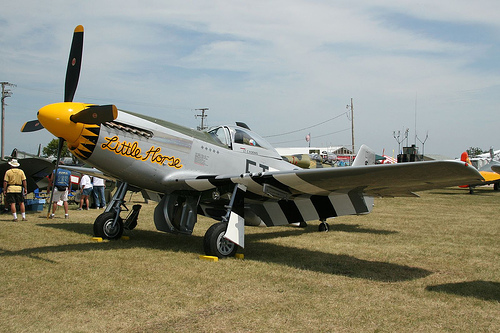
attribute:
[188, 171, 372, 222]
stripe — black, white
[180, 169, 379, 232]
stripes — black, white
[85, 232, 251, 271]
blocks — yellow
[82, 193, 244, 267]
wheels — black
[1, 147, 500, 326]
grass — greenish, brown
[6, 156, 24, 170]
hat — white, floppy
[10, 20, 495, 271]
airplane — white, yellow, black, grey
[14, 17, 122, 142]
propeller — black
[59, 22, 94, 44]
tips — yellow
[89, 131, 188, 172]
letters — cursive, yellow, black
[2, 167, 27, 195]
shirt — yellow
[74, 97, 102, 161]
triangle — yellow, black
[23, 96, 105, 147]
nose — yellow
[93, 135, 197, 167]
name — yellow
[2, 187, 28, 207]
shorts — black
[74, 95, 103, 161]
stripes — yellow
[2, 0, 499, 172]
sky — blue, white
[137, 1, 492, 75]
clouds — white, layered